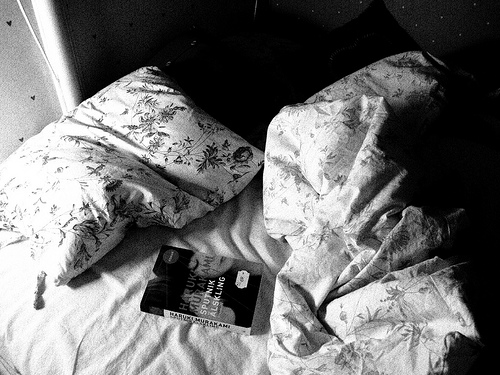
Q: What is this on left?
A: A pillow.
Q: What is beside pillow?
A: A book.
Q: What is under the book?
A: A sheet.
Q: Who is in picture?
A: No one.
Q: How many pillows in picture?
A: One.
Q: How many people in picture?
A: None.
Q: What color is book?
A: Mostly black.